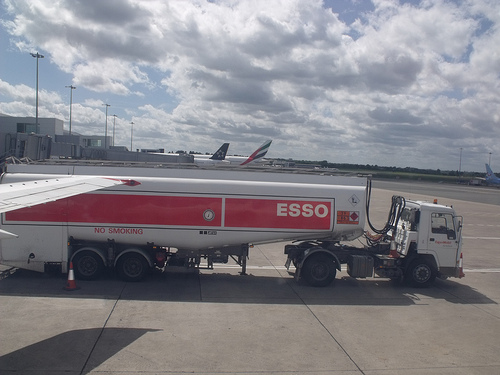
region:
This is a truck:
[0, 160, 470, 291]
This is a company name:
[267, 195, 327, 221]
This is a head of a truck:
[375, 185, 470, 290]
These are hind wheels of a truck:
[63, 243, 178, 283]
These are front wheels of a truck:
[293, 245, 443, 292]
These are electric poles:
[8, 80, 145, 159]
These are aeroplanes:
[134, 130, 499, 187]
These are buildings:
[0, 114, 130, 161]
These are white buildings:
[1, 112, 126, 157]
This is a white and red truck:
[0, 155, 477, 292]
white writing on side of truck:
[273, 200, 330, 220]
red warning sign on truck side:
[91, 222, 148, 238]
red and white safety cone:
[60, 259, 81, 290]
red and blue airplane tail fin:
[241, 142, 274, 167]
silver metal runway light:
[29, 50, 49, 118]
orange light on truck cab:
[426, 194, 443, 207]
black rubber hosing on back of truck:
[361, 170, 401, 237]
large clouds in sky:
[358, 27, 452, 116]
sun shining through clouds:
[123, 0, 253, 28]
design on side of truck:
[200, 209, 217, 223]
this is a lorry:
[146, 177, 451, 284]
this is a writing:
[98, 224, 144, 243]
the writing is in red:
[91, 227, 137, 236]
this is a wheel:
[307, 255, 332, 291]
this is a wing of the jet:
[13, 183, 64, 203]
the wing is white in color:
[31, 179, 53, 199]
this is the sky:
[16, 57, 49, 74]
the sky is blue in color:
[11, 61, 23, 71]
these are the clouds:
[178, 25, 297, 110]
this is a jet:
[181, 142, 270, 163]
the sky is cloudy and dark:
[217, 71, 448, 163]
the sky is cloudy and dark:
[213, 60, 357, 148]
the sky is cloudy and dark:
[155, 20, 326, 111]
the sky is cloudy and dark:
[213, 1, 350, 122]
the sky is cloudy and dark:
[229, 4, 316, 54]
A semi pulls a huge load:
[2, 157, 495, 292]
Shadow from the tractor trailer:
[85, 276, 490, 368]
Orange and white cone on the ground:
[54, 248, 104, 301]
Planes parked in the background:
[165, 135, 290, 167]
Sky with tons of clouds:
[282, 61, 445, 150]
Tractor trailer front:
[386, 177, 480, 299]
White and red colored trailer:
[150, 177, 365, 249]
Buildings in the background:
[6, 95, 203, 171]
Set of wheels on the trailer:
[67, 242, 168, 274]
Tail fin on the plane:
[242, 139, 291, 176]